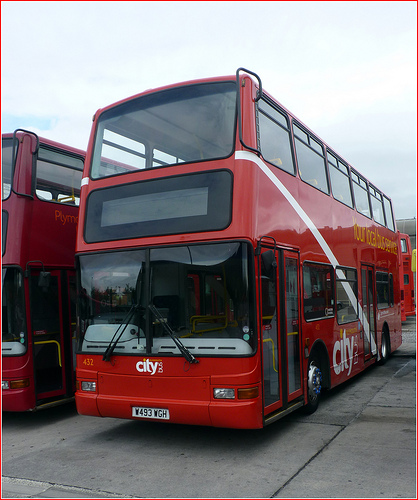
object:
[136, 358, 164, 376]
logo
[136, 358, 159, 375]
word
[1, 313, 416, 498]
floor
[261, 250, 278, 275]
reflector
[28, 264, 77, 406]
doors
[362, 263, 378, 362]
doors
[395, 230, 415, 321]
bus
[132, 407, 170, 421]
license plate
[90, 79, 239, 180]
windshield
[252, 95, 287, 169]
window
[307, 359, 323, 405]
rims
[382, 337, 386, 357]
rims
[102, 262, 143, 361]
blades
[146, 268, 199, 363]
blades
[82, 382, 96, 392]
headlight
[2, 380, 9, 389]
headlight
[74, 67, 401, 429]
bus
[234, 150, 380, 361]
white line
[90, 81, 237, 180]
window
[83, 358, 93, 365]
numbers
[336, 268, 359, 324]
window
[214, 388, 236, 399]
headlight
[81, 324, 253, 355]
dashboard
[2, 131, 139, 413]
bus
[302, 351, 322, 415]
tire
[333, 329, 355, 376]
word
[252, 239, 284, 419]
door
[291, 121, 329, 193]
window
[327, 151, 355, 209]
window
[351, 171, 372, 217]
window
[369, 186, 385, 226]
window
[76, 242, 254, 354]
windshield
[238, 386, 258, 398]
signal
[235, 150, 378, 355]
stripe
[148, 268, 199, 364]
wiper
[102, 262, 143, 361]
wiper